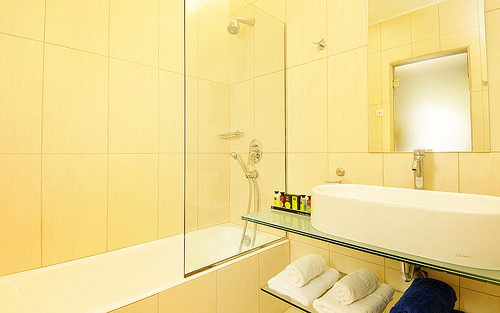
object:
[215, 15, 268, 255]
shower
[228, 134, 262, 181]
faucet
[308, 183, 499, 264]
sink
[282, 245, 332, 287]
towel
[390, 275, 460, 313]
towel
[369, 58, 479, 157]
mirror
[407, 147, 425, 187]
faucet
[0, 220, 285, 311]
tub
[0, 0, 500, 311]
bathroom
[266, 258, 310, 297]
towels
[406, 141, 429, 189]
tap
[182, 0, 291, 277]
glass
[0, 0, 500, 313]
tile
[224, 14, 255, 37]
shower head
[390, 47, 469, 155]
doorway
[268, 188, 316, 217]
items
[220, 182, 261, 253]
extender